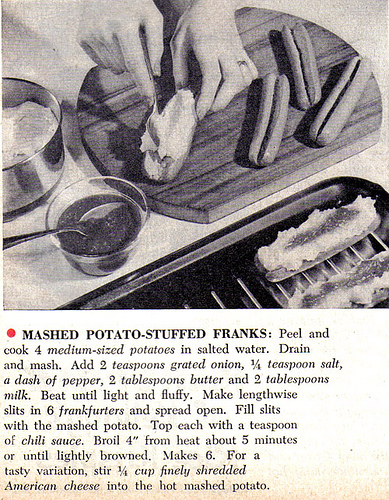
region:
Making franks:
[117, 63, 238, 209]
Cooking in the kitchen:
[65, 30, 323, 251]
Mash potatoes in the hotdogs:
[255, 206, 388, 304]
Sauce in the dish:
[21, 166, 186, 283]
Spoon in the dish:
[38, 178, 164, 270]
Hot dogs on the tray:
[222, 240, 382, 333]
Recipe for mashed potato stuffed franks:
[6, 318, 355, 466]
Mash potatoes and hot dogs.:
[27, 321, 192, 361]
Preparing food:
[118, 80, 241, 201]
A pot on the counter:
[7, 122, 91, 180]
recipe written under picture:
[3, 321, 346, 491]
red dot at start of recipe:
[6, 326, 19, 339]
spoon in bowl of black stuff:
[3, 201, 125, 251]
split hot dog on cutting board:
[248, 71, 289, 168]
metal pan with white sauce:
[4, 71, 65, 217]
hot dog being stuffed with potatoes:
[139, 86, 194, 186]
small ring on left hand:
[235, 58, 248, 69]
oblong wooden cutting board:
[75, 4, 382, 224]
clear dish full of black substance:
[44, 172, 150, 281]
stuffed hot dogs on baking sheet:
[55, 173, 388, 309]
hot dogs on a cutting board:
[249, 22, 361, 169]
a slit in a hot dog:
[258, 73, 283, 164]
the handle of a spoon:
[5, 221, 77, 241]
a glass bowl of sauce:
[40, 171, 160, 276]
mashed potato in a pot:
[7, 80, 40, 146]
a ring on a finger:
[233, 57, 250, 72]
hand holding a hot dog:
[90, 11, 242, 147]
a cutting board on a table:
[78, 89, 129, 142]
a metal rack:
[168, 272, 250, 304]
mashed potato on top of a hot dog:
[271, 211, 349, 244]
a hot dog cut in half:
[264, 23, 327, 108]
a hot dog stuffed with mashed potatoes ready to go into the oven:
[249, 191, 382, 282]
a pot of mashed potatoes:
[3, 60, 65, 215]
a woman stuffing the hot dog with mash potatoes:
[123, 77, 211, 188]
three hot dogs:
[239, 24, 374, 170]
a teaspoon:
[14, 174, 163, 283]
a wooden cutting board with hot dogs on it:
[74, 8, 382, 209]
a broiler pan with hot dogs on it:
[156, 182, 384, 303]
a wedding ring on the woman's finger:
[220, 44, 259, 82]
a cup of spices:
[25, 170, 170, 268]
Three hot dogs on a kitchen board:
[245, 14, 381, 168]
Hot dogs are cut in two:
[234, 12, 377, 173]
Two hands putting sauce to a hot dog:
[71, 0, 255, 185]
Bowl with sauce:
[37, 167, 157, 271]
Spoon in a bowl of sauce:
[3, 194, 105, 264]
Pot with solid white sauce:
[0, 66, 70, 219]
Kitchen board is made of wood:
[57, 2, 386, 223]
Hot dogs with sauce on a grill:
[247, 187, 385, 309]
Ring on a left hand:
[163, 1, 259, 115]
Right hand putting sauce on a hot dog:
[55, 3, 187, 164]